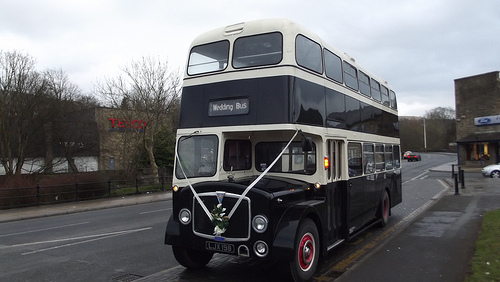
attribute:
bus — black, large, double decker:
[165, 17, 403, 281]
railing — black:
[0, 175, 174, 211]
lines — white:
[0, 153, 450, 277]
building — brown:
[454, 70, 499, 170]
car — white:
[481, 162, 499, 178]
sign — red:
[107, 116, 147, 130]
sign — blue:
[474, 115, 500, 126]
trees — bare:
[0, 50, 456, 187]